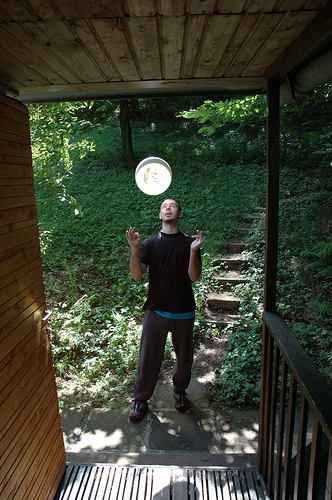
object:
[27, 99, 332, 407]
wooded area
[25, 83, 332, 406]
outside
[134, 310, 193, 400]
pants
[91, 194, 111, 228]
foliage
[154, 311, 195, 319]
blue shirt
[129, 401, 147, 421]
shoe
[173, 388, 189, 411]
shoe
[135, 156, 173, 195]
frisbee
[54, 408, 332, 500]
porch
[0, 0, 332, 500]
house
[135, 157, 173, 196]
pan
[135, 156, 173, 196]
pie pan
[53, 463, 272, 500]
floor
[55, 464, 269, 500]
slats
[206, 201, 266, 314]
stairs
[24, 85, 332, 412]
garden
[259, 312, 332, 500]
fence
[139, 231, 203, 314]
shirt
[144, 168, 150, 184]
bird picture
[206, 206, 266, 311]
slates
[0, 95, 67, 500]
pine siding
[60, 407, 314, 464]
cement slabs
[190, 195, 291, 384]
pathway steps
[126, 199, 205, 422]
boy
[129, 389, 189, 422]
tennis shoes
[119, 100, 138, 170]
tree